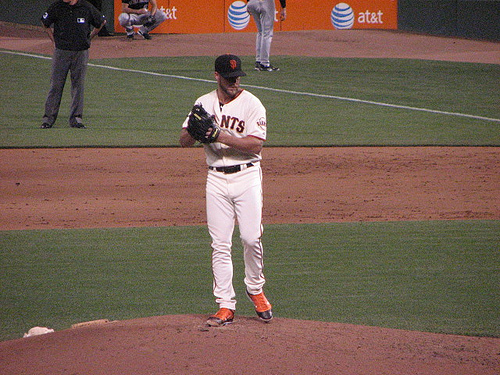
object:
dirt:
[93, 32, 495, 63]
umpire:
[39, 0, 106, 128]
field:
[0, 20, 499, 374]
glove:
[187, 105, 221, 144]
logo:
[331, 0, 355, 29]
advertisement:
[115, 0, 399, 34]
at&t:
[356, 10, 383, 26]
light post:
[330, 1, 392, 31]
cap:
[214, 53, 247, 79]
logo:
[229, 59, 236, 69]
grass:
[0, 215, 499, 343]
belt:
[206, 160, 259, 174]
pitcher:
[178, 54, 274, 326]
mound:
[0, 313, 499, 374]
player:
[115, 0, 170, 41]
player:
[245, 0, 286, 72]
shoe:
[244, 289, 273, 322]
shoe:
[207, 307, 237, 329]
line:
[0, 47, 499, 122]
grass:
[0, 46, 499, 143]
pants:
[246, 0, 272, 66]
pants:
[117, 8, 167, 37]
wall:
[288, 0, 395, 36]